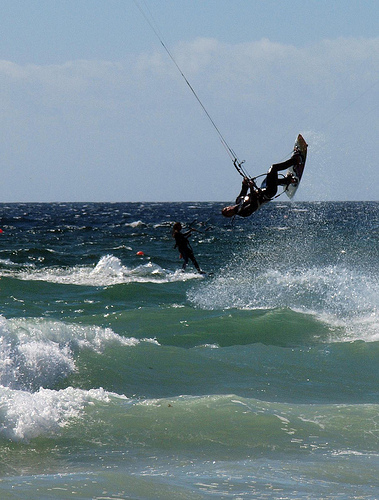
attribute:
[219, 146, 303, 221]
man — upside down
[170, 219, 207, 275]
person — upside down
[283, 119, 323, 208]
board — dark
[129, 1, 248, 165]
strings — long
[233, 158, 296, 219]
swimsuit — dark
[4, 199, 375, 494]
waves — clear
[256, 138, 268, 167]
ground — ocean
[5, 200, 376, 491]
water — blue, wavy, clear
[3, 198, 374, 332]
water — clear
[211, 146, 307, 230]
person — water skiing, upside down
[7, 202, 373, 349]
water — blue, clear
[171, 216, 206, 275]
woman — water skiing, upside down, clear, wavy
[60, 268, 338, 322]
water — blue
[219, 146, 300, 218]
surfer — upside down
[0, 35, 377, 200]
clouds — thin, white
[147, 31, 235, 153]
rope — long, thin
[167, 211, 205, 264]
person — upside down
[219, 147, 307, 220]
surfer — upside down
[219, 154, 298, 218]
surfer — upside down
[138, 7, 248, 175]
strings — long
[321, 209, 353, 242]
waves — white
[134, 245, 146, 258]
ball — red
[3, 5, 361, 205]
sky — blue, cloudy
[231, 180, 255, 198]
man strings — long